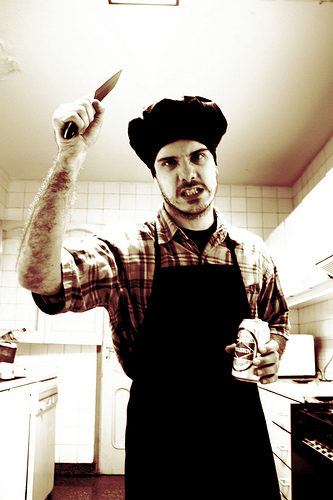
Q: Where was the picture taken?
A: It was taken at the kitchen.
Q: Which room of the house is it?
A: It is a kitchen.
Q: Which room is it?
A: It is a kitchen.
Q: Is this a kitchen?
A: Yes, it is a kitchen.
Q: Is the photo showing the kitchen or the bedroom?
A: It is showing the kitchen.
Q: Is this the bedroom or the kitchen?
A: It is the kitchen.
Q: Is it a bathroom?
A: No, it is a kitchen.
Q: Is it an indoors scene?
A: Yes, it is indoors.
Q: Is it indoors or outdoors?
A: It is indoors.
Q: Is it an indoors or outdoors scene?
A: It is indoors.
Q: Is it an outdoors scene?
A: No, it is indoors.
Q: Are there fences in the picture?
A: No, there are no fences.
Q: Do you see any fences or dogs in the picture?
A: No, there are no fences or dogs.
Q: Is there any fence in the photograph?
A: No, there are no fences.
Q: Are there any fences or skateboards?
A: No, there are no fences or skateboards.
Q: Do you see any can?
A: Yes, there is a can.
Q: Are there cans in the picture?
A: Yes, there is a can.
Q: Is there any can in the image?
A: Yes, there is a can.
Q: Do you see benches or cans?
A: Yes, there is a can.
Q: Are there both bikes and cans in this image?
A: No, there is a can but no bikes.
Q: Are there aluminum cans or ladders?
A: Yes, there is an aluminum can.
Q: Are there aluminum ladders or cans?
A: Yes, there is an aluminum can.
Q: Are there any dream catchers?
A: No, there are no dream catchers.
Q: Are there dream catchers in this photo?
A: No, there are no dream catchers.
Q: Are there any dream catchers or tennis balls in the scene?
A: No, there are no dream catchers or tennis balls.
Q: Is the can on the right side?
A: Yes, the can is on the right of the image.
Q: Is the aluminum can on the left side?
A: No, the can is on the right of the image.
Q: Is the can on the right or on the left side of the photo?
A: The can is on the right of the image.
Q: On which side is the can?
A: The can is on the right of the image.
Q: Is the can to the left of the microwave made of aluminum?
A: Yes, the can is made of aluminum.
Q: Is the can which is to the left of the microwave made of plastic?
A: No, the can is made of aluminum.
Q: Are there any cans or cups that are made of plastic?
A: No, there is a can but it is made of aluminum.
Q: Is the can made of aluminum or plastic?
A: The can is made of aluminum.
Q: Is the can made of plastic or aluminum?
A: The can is made of aluminum.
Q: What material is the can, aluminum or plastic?
A: The can is made of aluminum.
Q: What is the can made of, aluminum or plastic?
A: The can is made of aluminum.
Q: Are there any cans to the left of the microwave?
A: Yes, there is a can to the left of the microwave.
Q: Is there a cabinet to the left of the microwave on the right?
A: No, there is a can to the left of the microwave.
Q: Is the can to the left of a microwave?
A: Yes, the can is to the left of a microwave.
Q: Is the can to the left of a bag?
A: No, the can is to the left of a microwave.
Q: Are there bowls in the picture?
A: No, there are no bowls.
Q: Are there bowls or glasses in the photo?
A: No, there are no bowls or glasses.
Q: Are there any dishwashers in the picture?
A: Yes, there is a dishwasher.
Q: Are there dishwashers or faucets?
A: Yes, there is a dishwasher.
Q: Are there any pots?
A: No, there are no pots.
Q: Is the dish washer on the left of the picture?
A: Yes, the dish washer is on the left of the image.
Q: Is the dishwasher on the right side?
A: No, the dishwasher is on the left of the image.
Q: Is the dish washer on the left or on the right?
A: The dish washer is on the left of the image.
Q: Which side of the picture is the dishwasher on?
A: The dishwasher is on the left of the image.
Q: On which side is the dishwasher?
A: The dishwasher is on the left of the image.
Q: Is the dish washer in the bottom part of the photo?
A: Yes, the dish washer is in the bottom of the image.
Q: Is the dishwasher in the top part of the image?
A: No, the dishwasher is in the bottom of the image.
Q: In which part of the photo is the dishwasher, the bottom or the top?
A: The dishwasher is in the bottom of the image.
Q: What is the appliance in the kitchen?
A: The appliance is a dishwasher.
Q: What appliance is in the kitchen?
A: The appliance is a dishwasher.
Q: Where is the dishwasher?
A: The dishwasher is in the kitchen.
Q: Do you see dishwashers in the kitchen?
A: Yes, there is a dishwasher in the kitchen.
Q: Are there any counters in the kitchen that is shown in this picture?
A: No, there is a dishwasher in the kitchen.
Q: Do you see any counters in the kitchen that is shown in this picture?
A: No, there is a dishwasher in the kitchen.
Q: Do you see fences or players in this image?
A: No, there are no fences or players.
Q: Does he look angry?
A: Yes, the man is angry.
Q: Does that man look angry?
A: Yes, the man is angry.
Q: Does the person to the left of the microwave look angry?
A: Yes, the man is angry.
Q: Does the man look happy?
A: No, the man is angry.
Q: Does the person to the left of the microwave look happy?
A: No, the man is angry.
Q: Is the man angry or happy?
A: The man is angry.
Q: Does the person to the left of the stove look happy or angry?
A: The man is angry.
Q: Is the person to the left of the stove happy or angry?
A: The man is angry.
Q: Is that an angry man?
A: Yes, that is an angry man.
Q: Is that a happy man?
A: No, that is an angry man.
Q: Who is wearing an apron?
A: The man is wearing an apron.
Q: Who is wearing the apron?
A: The man is wearing an apron.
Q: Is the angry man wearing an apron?
A: Yes, the man is wearing an apron.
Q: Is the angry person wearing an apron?
A: Yes, the man is wearing an apron.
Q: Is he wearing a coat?
A: No, the man is wearing an apron.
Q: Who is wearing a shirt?
A: The man is wearing a shirt.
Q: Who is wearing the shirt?
A: The man is wearing a shirt.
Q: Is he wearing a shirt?
A: Yes, the man is wearing a shirt.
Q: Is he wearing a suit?
A: No, the man is wearing a shirt.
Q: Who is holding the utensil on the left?
A: The man is holding the knife.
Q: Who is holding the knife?
A: The man is holding the knife.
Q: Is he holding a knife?
A: Yes, the man is holding a knife.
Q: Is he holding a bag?
A: No, the man is holding a knife.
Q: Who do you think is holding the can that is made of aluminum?
A: The man is holding the can.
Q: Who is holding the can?
A: The man is holding the can.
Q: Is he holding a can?
A: Yes, the man is holding a can.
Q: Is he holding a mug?
A: No, the man is holding a can.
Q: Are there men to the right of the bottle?
A: Yes, there is a man to the right of the bottle.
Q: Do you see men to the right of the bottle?
A: Yes, there is a man to the right of the bottle.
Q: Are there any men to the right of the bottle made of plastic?
A: Yes, there is a man to the right of the bottle.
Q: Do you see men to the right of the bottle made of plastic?
A: Yes, there is a man to the right of the bottle.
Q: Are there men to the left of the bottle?
A: No, the man is to the right of the bottle.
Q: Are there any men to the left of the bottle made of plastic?
A: No, the man is to the right of the bottle.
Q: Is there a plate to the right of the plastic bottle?
A: No, there is a man to the right of the bottle.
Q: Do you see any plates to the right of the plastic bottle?
A: No, there is a man to the right of the bottle.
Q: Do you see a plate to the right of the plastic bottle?
A: No, there is a man to the right of the bottle.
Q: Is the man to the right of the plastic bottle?
A: Yes, the man is to the right of the bottle.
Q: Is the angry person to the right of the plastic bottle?
A: Yes, the man is to the right of the bottle.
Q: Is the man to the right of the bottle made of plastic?
A: Yes, the man is to the right of the bottle.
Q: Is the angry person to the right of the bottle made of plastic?
A: Yes, the man is to the right of the bottle.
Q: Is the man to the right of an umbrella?
A: No, the man is to the right of the bottle.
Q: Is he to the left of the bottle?
A: No, the man is to the right of the bottle.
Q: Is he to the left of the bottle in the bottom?
A: No, the man is to the right of the bottle.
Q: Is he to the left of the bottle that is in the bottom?
A: No, the man is to the right of the bottle.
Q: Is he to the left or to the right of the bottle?
A: The man is to the right of the bottle.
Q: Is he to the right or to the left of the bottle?
A: The man is to the right of the bottle.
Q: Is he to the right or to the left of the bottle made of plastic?
A: The man is to the right of the bottle.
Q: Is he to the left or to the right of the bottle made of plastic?
A: The man is to the right of the bottle.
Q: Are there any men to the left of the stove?
A: Yes, there is a man to the left of the stove.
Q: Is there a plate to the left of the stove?
A: No, there is a man to the left of the stove.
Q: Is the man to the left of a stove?
A: Yes, the man is to the left of a stove.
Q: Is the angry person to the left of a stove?
A: Yes, the man is to the left of a stove.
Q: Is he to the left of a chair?
A: No, the man is to the left of a stove.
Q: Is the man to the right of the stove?
A: No, the man is to the left of the stove.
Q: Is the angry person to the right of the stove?
A: No, the man is to the left of the stove.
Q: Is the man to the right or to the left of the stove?
A: The man is to the left of the stove.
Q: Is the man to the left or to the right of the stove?
A: The man is to the left of the stove.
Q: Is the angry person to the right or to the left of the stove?
A: The man is to the left of the stove.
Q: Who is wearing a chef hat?
A: The man is wearing a chef hat.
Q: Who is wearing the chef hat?
A: The man is wearing a chef hat.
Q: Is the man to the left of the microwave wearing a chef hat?
A: Yes, the man is wearing a chef hat.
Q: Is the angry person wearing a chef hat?
A: Yes, the man is wearing a chef hat.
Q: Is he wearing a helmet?
A: No, the man is wearing a chef hat.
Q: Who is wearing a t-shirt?
A: The man is wearing a t-shirt.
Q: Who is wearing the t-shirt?
A: The man is wearing a t-shirt.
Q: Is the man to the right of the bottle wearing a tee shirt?
A: Yes, the man is wearing a tee shirt.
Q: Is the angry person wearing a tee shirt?
A: Yes, the man is wearing a tee shirt.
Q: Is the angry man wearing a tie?
A: No, the man is wearing a tee shirt.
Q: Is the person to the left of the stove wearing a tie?
A: No, the man is wearing a tee shirt.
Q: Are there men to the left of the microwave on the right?
A: Yes, there is a man to the left of the microwave.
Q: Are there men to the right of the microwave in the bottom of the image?
A: No, the man is to the left of the microwave.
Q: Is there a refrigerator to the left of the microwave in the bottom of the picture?
A: No, there is a man to the left of the microwave.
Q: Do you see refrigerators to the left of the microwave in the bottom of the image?
A: No, there is a man to the left of the microwave.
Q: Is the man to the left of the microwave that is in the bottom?
A: Yes, the man is to the left of the microwave.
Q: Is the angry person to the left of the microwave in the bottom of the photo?
A: Yes, the man is to the left of the microwave.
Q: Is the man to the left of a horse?
A: No, the man is to the left of the microwave.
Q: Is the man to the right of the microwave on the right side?
A: No, the man is to the left of the microwave.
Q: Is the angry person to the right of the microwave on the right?
A: No, the man is to the left of the microwave.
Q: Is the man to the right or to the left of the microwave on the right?
A: The man is to the left of the microwave.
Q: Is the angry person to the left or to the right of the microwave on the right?
A: The man is to the left of the microwave.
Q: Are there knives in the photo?
A: Yes, there is a knife.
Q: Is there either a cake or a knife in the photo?
A: Yes, there is a knife.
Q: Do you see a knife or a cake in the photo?
A: Yes, there is a knife.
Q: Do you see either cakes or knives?
A: Yes, there is a knife.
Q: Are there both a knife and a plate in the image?
A: No, there is a knife but no plates.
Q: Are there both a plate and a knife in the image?
A: No, there is a knife but no plates.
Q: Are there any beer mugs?
A: No, there are no beer mugs.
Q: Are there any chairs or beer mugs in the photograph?
A: No, there are no beer mugs or chairs.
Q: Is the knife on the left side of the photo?
A: Yes, the knife is on the left of the image.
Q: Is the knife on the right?
A: No, the knife is on the left of the image.